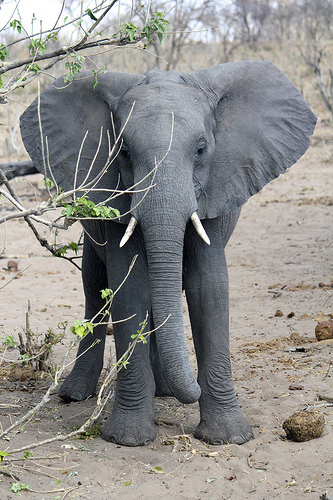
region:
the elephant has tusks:
[24, 74, 292, 319]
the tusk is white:
[182, 200, 249, 260]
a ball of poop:
[243, 388, 330, 467]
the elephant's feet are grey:
[100, 306, 286, 480]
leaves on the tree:
[58, 287, 156, 405]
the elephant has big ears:
[10, 35, 321, 298]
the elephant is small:
[10, 27, 323, 454]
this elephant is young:
[14, 6, 319, 456]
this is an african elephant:
[11, 7, 325, 457]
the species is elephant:
[7, 11, 325, 462]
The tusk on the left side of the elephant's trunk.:
[121, 209, 135, 253]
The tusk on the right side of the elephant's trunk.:
[188, 212, 211, 243]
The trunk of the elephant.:
[145, 229, 207, 410]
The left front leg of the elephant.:
[109, 225, 162, 443]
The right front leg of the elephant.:
[182, 227, 252, 443]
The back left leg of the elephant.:
[59, 226, 101, 404]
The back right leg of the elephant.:
[151, 312, 189, 396]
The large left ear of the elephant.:
[9, 74, 132, 219]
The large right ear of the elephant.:
[197, 55, 315, 219]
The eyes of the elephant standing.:
[116, 138, 208, 167]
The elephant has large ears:
[30, 57, 303, 225]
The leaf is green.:
[65, 189, 115, 227]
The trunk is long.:
[135, 178, 216, 409]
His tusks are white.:
[102, 196, 239, 269]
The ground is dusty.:
[261, 226, 332, 461]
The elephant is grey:
[44, 105, 195, 221]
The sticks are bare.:
[27, 76, 178, 218]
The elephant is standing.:
[51, 65, 293, 461]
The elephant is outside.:
[55, 104, 309, 469]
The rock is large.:
[281, 404, 321, 446]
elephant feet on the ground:
[28, 369, 271, 466]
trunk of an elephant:
[139, 227, 203, 420]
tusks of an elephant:
[115, 208, 209, 254]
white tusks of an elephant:
[109, 207, 217, 253]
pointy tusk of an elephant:
[184, 204, 214, 263]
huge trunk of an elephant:
[129, 231, 206, 412]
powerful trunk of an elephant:
[131, 227, 198, 417]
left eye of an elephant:
[192, 133, 213, 174]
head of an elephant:
[19, 54, 311, 236]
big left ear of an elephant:
[205, 55, 319, 212]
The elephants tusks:
[117, 212, 216, 253]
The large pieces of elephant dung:
[279, 314, 331, 441]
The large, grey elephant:
[2, 56, 316, 447]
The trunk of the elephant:
[134, 196, 205, 411]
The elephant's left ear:
[196, 56, 320, 218]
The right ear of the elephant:
[12, 59, 138, 230]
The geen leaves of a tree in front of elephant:
[0, 0, 195, 499]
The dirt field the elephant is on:
[0, 128, 331, 499]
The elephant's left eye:
[188, 131, 209, 163]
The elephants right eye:
[114, 143, 135, 162]